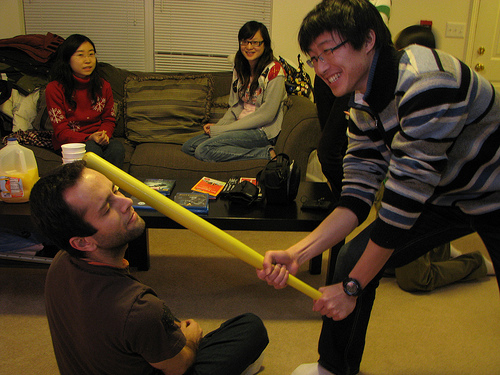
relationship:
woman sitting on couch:
[204, 20, 335, 181] [74, 59, 334, 196]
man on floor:
[29, 160, 269, 375] [0, 202, 498, 374]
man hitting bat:
[20, 166, 191, 356] [81, 146, 341, 321]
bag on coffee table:
[254, 150, 299, 206] [0, 178, 333, 276]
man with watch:
[258, 0, 499, 375] [343, 276, 364, 299]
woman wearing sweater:
[43, 34, 126, 178] [39, 73, 126, 137]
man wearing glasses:
[258, 0, 500, 375] [304, 38, 352, 65]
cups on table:
[61, 143, 87, 164] [20, 157, 352, 287]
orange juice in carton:
[2, 167, 36, 199] [0, 135, 42, 206]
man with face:
[258, 0, 499, 375] [304, 32, 366, 95]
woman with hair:
[42, 30, 158, 172] [55, 27, 115, 108]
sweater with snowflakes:
[58, 77, 142, 134] [42, 82, 117, 139]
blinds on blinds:
[33, 8, 264, 75] [22, 0, 271, 74]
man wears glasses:
[258, 0, 500, 375] [304, 38, 352, 65]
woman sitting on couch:
[180, 20, 287, 164] [2, 49, 325, 199]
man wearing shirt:
[29, 160, 269, 375] [37, 236, 187, 371]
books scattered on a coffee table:
[109, 171, 281, 223] [0, 159, 351, 281]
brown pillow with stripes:
[133, 72, 246, 152] [123, 78, 208, 142]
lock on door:
[469, 40, 483, 71] [128, 13, 275, 93]